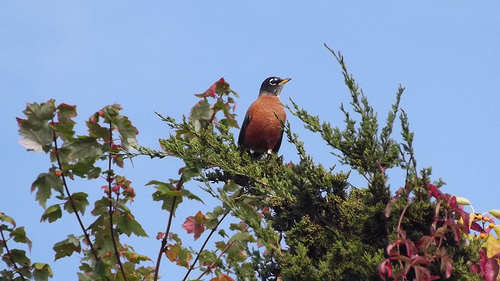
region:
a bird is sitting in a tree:
[224, 62, 304, 179]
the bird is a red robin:
[236, 74, 292, 164]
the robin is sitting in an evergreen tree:
[166, 47, 416, 277]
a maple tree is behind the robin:
[6, 72, 296, 277]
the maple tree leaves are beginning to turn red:
[5, 75, 285, 276]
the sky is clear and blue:
[5, 5, 495, 265]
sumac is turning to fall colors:
[381, 170, 497, 275]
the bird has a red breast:
[235, 71, 295, 164]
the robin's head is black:
[256, 71, 284, 98]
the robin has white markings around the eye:
[266, 74, 281, 89]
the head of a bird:
[256, 68, 294, 98]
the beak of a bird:
[276, 73, 293, 85]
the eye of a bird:
[268, 73, 279, 87]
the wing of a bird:
[236, 100, 254, 150]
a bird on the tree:
[226, 72, 295, 162]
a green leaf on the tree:
[12, 113, 58, 153]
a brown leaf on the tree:
[181, 208, 211, 241]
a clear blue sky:
[0, 0, 499, 280]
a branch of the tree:
[145, 169, 189, 279]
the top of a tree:
[90, 23, 489, 278]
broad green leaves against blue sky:
[56, 123, 151, 274]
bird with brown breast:
[233, 58, 300, 163]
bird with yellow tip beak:
[248, 66, 303, 138]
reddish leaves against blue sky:
[366, 151, 494, 280]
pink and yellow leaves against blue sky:
[438, 164, 497, 248]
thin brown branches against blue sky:
[37, 152, 194, 274]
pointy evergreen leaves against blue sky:
[288, 29, 406, 169]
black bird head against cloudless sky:
[231, 6, 298, 98]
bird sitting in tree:
[235, 38, 294, 189]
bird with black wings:
[236, 48, 297, 163]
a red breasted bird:
[227, 57, 307, 172]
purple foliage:
[368, 166, 498, 273]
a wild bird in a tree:
[180, 23, 424, 254]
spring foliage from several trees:
[7, 7, 484, 259]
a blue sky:
[15, 15, 389, 60]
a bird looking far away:
[262, 72, 309, 97]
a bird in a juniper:
[200, 67, 369, 279]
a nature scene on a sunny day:
[20, 5, 477, 250]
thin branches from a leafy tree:
[35, 125, 163, 277]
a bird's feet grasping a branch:
[235, 143, 291, 183]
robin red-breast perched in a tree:
[239, 68, 299, 183]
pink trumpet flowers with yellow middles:
[361, 171, 496, 277]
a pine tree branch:
[151, 113, 408, 246]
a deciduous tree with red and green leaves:
[9, 103, 164, 254]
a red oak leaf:
[194, 81, 230, 108]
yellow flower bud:
[460, 196, 496, 258]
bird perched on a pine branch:
[151, 40, 366, 236]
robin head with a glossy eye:
[263, 72, 301, 96]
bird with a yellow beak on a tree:
[241, 64, 308, 177]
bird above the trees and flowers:
[89, 41, 442, 246]